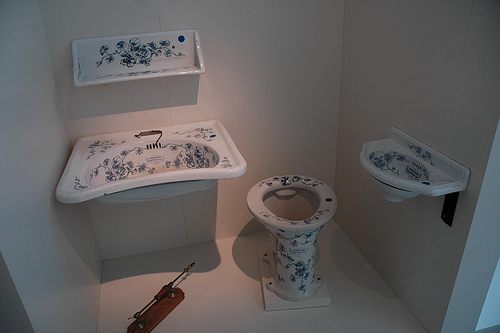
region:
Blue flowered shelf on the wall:
[65, 30, 210, 85]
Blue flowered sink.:
[50, 115, 245, 205]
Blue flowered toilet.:
[240, 166, 350, 311]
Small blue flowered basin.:
[355, 121, 470, 211]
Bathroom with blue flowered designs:
[5, 11, 485, 326]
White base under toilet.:
[255, 245, 335, 307]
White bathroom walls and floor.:
[1, 10, 491, 327]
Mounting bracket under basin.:
[440, 186, 460, 227]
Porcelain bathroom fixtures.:
[47, 25, 472, 302]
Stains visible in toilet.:
[268, 192, 319, 218]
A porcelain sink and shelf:
[42, 15, 254, 218]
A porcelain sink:
[362, 123, 471, 215]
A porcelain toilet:
[248, 162, 342, 332]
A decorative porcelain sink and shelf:
[45, 22, 247, 226]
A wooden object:
[119, 259, 206, 331]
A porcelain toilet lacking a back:
[242, 157, 348, 332]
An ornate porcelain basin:
[356, 110, 480, 223]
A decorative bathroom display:
[52, 17, 467, 332]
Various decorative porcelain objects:
[51, 24, 498, 329]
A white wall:
[253, 5, 356, 172]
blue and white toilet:
[244, 172, 340, 299]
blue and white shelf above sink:
[70, 26, 205, 88]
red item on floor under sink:
[126, 258, 196, 330]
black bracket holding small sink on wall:
[438, 191, 460, 229]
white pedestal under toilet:
[256, 246, 332, 313]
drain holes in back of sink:
[143, 140, 163, 150]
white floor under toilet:
[97, 210, 434, 330]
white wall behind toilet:
[39, 0, 349, 261]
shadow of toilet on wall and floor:
[232, 215, 275, 280]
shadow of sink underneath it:
[50, 181, 223, 282]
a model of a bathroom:
[0, 2, 498, 329]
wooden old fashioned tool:
[111, 257, 205, 327]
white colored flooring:
[97, 198, 432, 331]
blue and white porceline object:
[243, 170, 339, 308]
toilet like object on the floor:
[246, 167, 344, 311]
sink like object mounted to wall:
[356, 122, 473, 216]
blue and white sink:
[356, 115, 478, 218]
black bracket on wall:
[441, 187, 461, 232]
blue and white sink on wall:
[56, 127, 248, 208]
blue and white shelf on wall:
[61, 24, 216, 95]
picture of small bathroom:
[54, 11, 461, 328]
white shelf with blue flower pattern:
[61, 26, 216, 95]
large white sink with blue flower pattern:
[60, 113, 238, 215]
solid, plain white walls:
[250, 22, 322, 141]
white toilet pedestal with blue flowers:
[255, 165, 342, 318]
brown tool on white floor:
[122, 248, 207, 330]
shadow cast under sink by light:
[57, 202, 220, 299]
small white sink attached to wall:
[325, 126, 475, 216]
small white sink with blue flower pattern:
[330, 119, 482, 216]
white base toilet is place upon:
[259, 236, 325, 321]